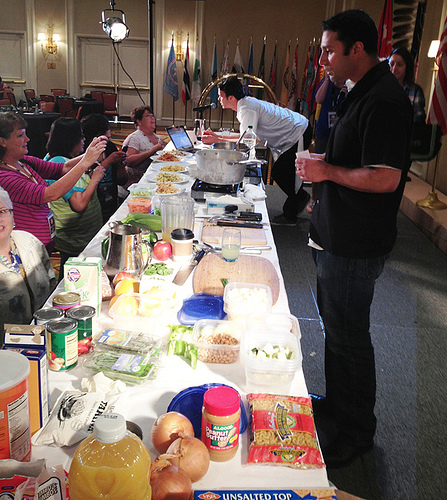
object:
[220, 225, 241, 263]
glass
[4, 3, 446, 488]
room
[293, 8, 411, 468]
man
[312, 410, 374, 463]
shoes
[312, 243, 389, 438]
pants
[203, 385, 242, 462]
jar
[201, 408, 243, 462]
peanuts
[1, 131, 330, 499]
table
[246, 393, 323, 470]
pasta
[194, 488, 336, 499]
box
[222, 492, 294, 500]
white printing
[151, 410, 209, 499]
onions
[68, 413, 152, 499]
orange juice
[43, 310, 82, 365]
cans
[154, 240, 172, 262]
apple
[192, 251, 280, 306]
cutting board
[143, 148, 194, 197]
plates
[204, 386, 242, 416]
lid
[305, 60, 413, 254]
shirt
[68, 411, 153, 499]
bottle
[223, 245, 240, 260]
juice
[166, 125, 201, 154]
laptop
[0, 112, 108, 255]
woman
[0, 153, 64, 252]
striped shirt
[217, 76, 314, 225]
person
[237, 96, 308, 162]
white shirt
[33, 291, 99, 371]
food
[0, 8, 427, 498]
people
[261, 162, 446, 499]
floor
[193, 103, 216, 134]
microphone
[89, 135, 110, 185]
pictures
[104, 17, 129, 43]
light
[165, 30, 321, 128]
flags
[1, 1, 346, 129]
wall